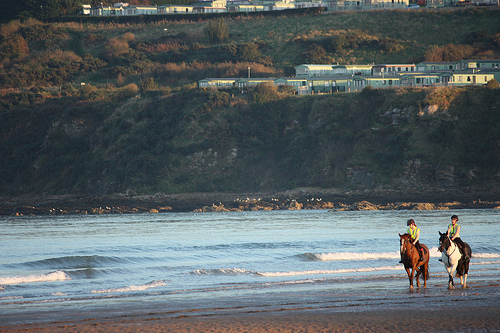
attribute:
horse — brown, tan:
[398, 233, 429, 293]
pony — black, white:
[438, 230, 472, 289]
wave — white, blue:
[7, 253, 197, 269]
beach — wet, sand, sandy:
[0, 299, 498, 332]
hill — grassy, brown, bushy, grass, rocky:
[1, 89, 498, 210]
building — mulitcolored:
[351, 72, 401, 90]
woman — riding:
[407, 218, 425, 261]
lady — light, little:
[445, 214, 466, 262]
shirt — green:
[407, 225, 420, 239]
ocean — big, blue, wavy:
[0, 207, 499, 315]